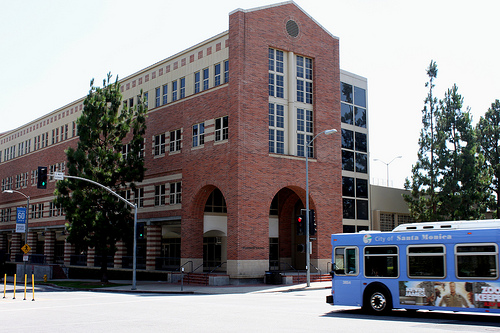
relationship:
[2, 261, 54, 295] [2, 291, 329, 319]
poles in street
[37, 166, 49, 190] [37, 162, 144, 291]
green stoplight attached to a pole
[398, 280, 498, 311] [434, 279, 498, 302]
ad for zookeeper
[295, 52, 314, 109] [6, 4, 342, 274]
window on building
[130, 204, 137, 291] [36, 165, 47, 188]
pole holding traffic signal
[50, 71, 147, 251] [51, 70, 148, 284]
leaves on tree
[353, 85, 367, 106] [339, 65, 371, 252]
window in building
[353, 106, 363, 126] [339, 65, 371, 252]
window in building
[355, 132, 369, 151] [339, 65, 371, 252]
window in building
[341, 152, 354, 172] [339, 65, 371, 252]
window in building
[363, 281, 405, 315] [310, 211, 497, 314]
chrome wheel on bus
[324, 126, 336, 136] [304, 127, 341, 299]
light on pole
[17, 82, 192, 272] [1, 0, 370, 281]
tree near building